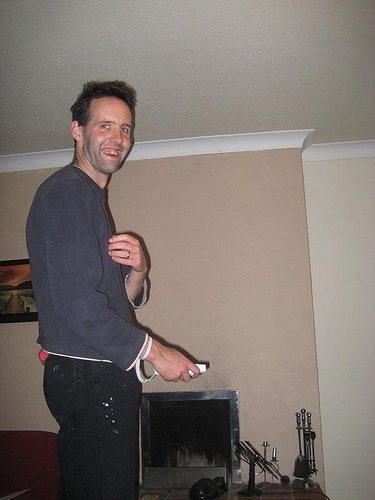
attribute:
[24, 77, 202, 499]
man — smiling, standing, playing video game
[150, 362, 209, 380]
remote — white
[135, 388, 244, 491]
fireplace — off, silver, black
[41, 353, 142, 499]
pants — black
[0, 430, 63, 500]
couch — red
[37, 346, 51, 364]
object — red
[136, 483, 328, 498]
floor — red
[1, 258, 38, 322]
painting — framed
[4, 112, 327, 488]
wall — tan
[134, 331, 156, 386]
strap — white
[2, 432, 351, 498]
chair — red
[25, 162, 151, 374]
shirt — grey, long sleeved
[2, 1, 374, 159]
ceiling — white